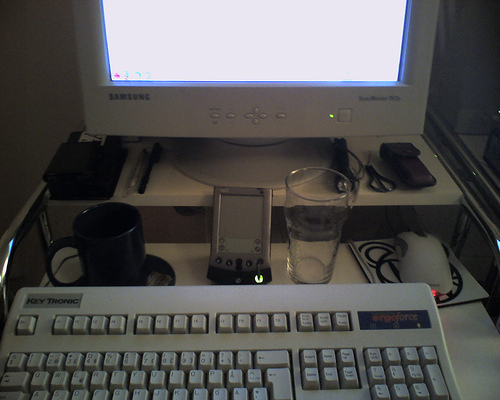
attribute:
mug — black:
[37, 196, 151, 290]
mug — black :
[41, 204, 140, 284]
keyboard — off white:
[14, 268, 456, 395]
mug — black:
[44, 200, 149, 289]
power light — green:
[324, 109, 336, 121]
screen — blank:
[101, 1, 407, 82]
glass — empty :
[281, 160, 351, 282]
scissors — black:
[348, 143, 423, 229]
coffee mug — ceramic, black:
[41, 191, 171, 293]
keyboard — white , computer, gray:
[1, 277, 466, 398]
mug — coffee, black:
[49, 190, 175, 293]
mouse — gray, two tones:
[398, 226, 455, 292]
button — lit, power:
[326, 103, 353, 123]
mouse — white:
[394, 228, 455, 298]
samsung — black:
[101, 85, 155, 107]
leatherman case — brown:
[377, 136, 441, 199]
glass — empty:
[278, 165, 345, 288]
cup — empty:
[37, 198, 150, 290]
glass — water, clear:
[266, 160, 370, 277]